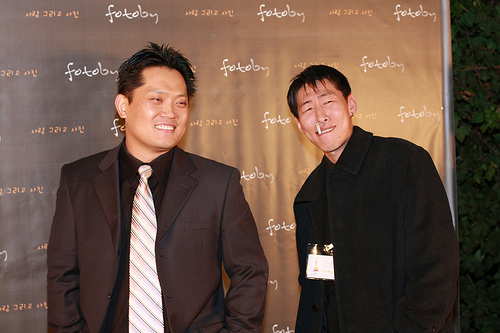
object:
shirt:
[104, 144, 174, 333]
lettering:
[217, 57, 270, 77]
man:
[45, 40, 273, 333]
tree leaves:
[456, 10, 475, 27]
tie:
[126, 165, 165, 332]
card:
[304, 252, 337, 280]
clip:
[322, 241, 336, 256]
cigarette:
[315, 119, 323, 135]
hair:
[118, 41, 200, 105]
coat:
[290, 123, 461, 332]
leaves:
[470, 114, 490, 131]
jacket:
[45, 144, 271, 333]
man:
[286, 64, 464, 332]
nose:
[159, 97, 177, 120]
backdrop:
[0, 0, 455, 333]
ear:
[113, 92, 128, 118]